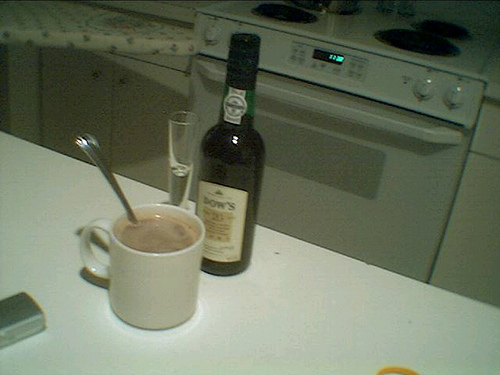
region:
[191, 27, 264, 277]
a green bottle on a table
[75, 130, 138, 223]
a spoon in a mug of coffee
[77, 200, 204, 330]
a white mug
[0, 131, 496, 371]
a white table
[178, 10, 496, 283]
a white kitchen stove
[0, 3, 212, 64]
an ironing board next to a stove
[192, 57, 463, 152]
the handle of an oven door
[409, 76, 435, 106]
a knob on a stove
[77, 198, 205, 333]
Cup of coffee on the table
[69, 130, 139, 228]
Silver spoon in the cup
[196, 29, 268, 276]
Bottle of alcohol beverege on the table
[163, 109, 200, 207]
Shot glass near the cup of coffee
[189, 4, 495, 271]
White cooking stove near the table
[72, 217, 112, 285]
White handle of the cup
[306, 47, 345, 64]
Digital indicator of the cooking stove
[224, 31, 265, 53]
Cap of the bottle of beverege alcohol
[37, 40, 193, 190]
Cabinet cupboard near the cooking stove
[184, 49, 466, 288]
Oven area of the cooling stove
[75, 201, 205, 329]
White cup on the table.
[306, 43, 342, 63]
Digital light on the stove.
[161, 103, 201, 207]
Clear fluted glass on table.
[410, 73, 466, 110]
White knobs on the oven.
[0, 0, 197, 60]
Ironing board by cabinet.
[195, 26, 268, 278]
Bottle on the table.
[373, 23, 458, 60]
Burner on the stove.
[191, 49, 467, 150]
White handle on the stove.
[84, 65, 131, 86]
Knobs on the cabinet.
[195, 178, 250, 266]
label on the bottle.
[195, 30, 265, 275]
Glass bottle on a table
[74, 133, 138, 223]
A utencil in a mug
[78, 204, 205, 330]
A white mug on a table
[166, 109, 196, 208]
A small glass on a table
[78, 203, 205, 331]
A mug full of a drink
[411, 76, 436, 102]
A burner switch on a stove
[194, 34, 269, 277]
Alcohol bottle on a table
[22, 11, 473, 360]
coffe and wine on the table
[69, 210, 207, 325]
a cup of coffee in a white mug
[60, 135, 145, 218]
a spoon is in the coffee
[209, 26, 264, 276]
a wine bottle on the table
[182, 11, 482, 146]
an oven in the kitchen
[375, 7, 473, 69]
electric burners on a stove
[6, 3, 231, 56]
an iron board in the background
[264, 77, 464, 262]
an oven door on the stove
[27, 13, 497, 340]
the basic color design of this kitchen is white